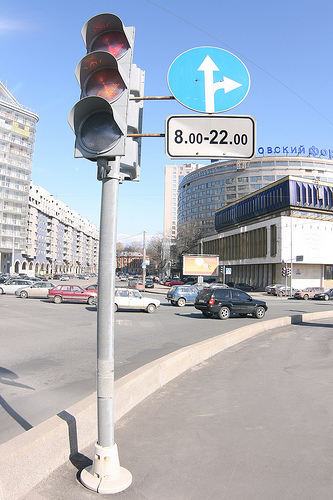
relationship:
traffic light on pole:
[67, 10, 147, 184] [93, 174, 121, 454]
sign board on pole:
[165, 43, 253, 117] [93, 174, 121, 454]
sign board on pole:
[163, 113, 258, 163] [93, 174, 121, 454]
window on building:
[225, 175, 238, 185] [173, 154, 332, 255]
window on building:
[204, 179, 214, 190] [173, 154, 332, 255]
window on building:
[262, 174, 280, 184] [173, 154, 332, 255]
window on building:
[247, 159, 263, 169] [173, 154, 332, 255]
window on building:
[301, 160, 317, 166] [173, 154, 332, 255]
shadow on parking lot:
[1, 365, 95, 476] [0, 270, 333, 444]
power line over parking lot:
[144, 0, 333, 126] [0, 270, 333, 444]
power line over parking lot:
[118, 230, 146, 243] [0, 270, 333, 444]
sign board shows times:
[163, 113, 258, 163] [175, 129, 248, 145]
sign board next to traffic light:
[165, 43, 253, 117] [67, 10, 147, 184]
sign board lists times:
[163, 113, 258, 163] [172, 124, 250, 149]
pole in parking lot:
[93, 174, 121, 454] [0, 270, 333, 444]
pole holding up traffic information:
[93, 174, 121, 454] [163, 44, 257, 160]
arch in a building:
[13, 258, 21, 281] [0, 80, 116, 279]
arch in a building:
[21, 259, 29, 273] [0, 80, 116, 279]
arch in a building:
[45, 260, 53, 278] [0, 80, 116, 279]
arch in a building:
[32, 260, 42, 281] [0, 80, 116, 279]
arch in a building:
[54, 262, 60, 277] [0, 80, 116, 279]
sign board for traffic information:
[165, 43, 253, 117] [163, 44, 257, 160]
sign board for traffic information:
[163, 113, 258, 163] [163, 44, 257, 160]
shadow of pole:
[1, 365, 95, 476] [93, 174, 121, 454]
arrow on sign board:
[197, 52, 222, 112] [165, 43, 253, 117]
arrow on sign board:
[210, 71, 244, 98] [165, 43, 253, 117]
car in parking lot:
[43, 281, 101, 308] [2, 270, 329, 444]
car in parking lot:
[91, 286, 162, 318] [2, 270, 329, 444]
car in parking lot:
[167, 283, 203, 309] [2, 270, 329, 444]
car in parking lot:
[13, 277, 60, 300] [2, 270, 329, 444]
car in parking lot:
[1, 275, 37, 298] [2, 270, 329, 444]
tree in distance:
[146, 238, 168, 276] [99, 236, 185, 283]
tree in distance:
[118, 243, 134, 272] [99, 236, 185, 283]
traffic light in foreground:
[67, 10, 147, 184] [10, 13, 328, 490]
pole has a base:
[93, 174, 121, 454] [76, 440, 134, 500]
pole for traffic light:
[93, 174, 121, 454] [67, 10, 147, 184]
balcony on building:
[13, 119, 31, 138] [0, 80, 116, 279]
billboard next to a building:
[178, 253, 220, 278] [173, 154, 332, 255]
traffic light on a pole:
[67, 10, 147, 184] [93, 174, 121, 454]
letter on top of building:
[295, 143, 306, 156] [173, 154, 332, 255]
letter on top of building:
[282, 145, 290, 157] [173, 154, 332, 255]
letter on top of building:
[273, 146, 282, 158] [173, 154, 332, 255]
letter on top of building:
[265, 145, 274, 157] [173, 154, 332, 255]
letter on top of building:
[257, 146, 267, 157] [173, 154, 332, 255]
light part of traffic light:
[77, 10, 139, 63] [67, 10, 147, 184]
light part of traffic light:
[83, 64, 128, 106] [67, 10, 147, 184]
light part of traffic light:
[76, 108, 123, 155] [67, 10, 147, 184]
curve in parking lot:
[4, 309, 333, 498] [0, 270, 333, 444]